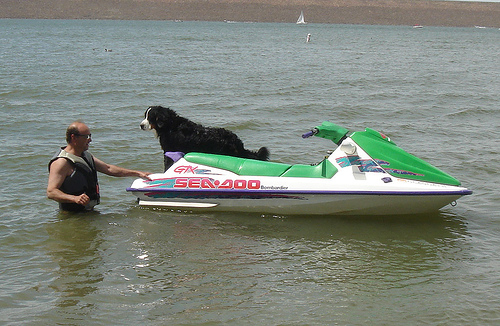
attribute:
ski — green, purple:
[125, 119, 474, 219]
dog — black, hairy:
[139, 104, 270, 168]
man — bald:
[45, 120, 153, 216]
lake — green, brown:
[1, 19, 499, 325]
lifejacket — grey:
[47, 143, 102, 209]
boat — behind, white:
[296, 9, 307, 27]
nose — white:
[139, 118, 154, 131]